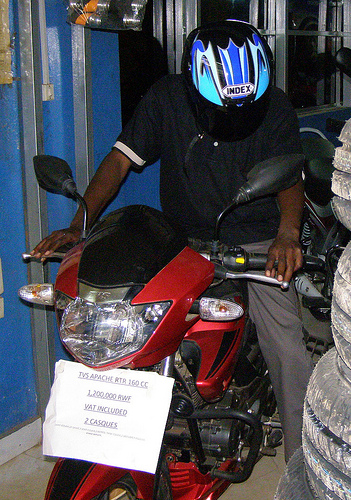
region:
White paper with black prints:
[40, 353, 178, 475]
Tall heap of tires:
[267, 111, 350, 499]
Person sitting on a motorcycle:
[14, 15, 349, 498]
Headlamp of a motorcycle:
[47, 269, 178, 376]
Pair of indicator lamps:
[16, 279, 245, 325]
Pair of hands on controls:
[14, 223, 328, 291]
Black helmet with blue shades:
[175, 14, 279, 145]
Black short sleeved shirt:
[107, 71, 309, 254]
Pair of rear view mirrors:
[23, 145, 311, 244]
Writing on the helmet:
[218, 83, 260, 96]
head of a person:
[163, 24, 283, 141]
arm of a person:
[62, 151, 159, 224]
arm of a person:
[262, 162, 322, 243]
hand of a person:
[29, 205, 95, 268]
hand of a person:
[243, 233, 328, 302]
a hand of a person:
[25, 215, 99, 260]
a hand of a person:
[259, 234, 331, 286]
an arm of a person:
[74, 131, 165, 228]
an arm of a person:
[255, 153, 333, 236]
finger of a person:
[35, 228, 70, 252]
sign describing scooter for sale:
[38, 358, 172, 474]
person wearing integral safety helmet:
[183, 17, 274, 145]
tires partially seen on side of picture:
[277, 118, 350, 498]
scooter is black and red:
[26, 208, 257, 496]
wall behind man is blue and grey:
[0, 2, 121, 149]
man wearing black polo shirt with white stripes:
[108, 55, 311, 241]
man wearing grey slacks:
[222, 234, 315, 464]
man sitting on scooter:
[38, 22, 305, 449]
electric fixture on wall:
[40, 0, 57, 102]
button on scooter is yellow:
[232, 254, 246, 267]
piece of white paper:
[44, 360, 172, 473]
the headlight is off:
[51, 291, 169, 362]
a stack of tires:
[275, 115, 349, 498]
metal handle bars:
[227, 271, 288, 288]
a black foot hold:
[188, 408, 262, 483]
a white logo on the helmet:
[221, 84, 255, 96]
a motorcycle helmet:
[181, 19, 272, 138]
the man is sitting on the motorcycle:
[30, 22, 310, 454]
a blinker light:
[197, 296, 243, 319]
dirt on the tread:
[314, 437, 330, 455]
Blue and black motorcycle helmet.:
[180, 18, 276, 144]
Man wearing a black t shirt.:
[25, 18, 311, 463]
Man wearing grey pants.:
[31, 20, 311, 465]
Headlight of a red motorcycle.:
[57, 296, 143, 365]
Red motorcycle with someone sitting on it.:
[18, 153, 323, 498]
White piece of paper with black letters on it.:
[38, 359, 177, 479]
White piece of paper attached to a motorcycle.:
[41, 358, 175, 475]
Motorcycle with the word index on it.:
[181, 20, 274, 142]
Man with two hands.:
[30, 18, 314, 466]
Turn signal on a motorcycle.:
[18, 278, 54, 314]